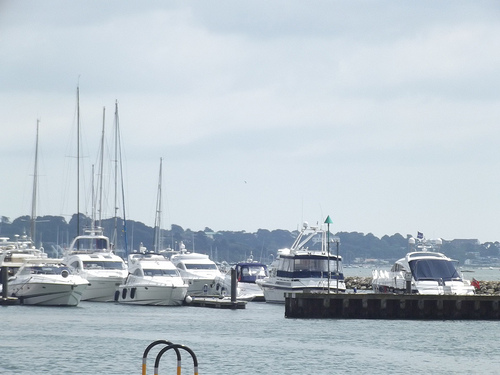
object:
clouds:
[0, 0, 497, 197]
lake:
[6, 302, 497, 373]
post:
[25, 82, 174, 258]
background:
[0, 0, 499, 237]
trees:
[391, 233, 404, 256]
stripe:
[21, 291, 87, 300]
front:
[25, 274, 88, 307]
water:
[1, 304, 497, 374]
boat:
[392, 243, 484, 335]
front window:
[404, 257, 457, 280]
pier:
[270, 249, 497, 344]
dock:
[285, 291, 498, 321]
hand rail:
[136, 334, 201, 372]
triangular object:
[322, 215, 332, 227]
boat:
[6, 260, 91, 310]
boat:
[63, 163, 125, 300]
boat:
[116, 250, 187, 306]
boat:
[171, 250, 226, 297]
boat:
[253, 220, 348, 302]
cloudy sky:
[0, 0, 499, 230]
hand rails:
[138, 335, 200, 372]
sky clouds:
[0, 8, 499, 211]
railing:
[306, 291, 344, 295]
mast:
[71, 84, 83, 252]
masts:
[147, 155, 169, 255]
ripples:
[0, 321, 500, 373]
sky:
[1, 0, 490, 235]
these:
[28, 116, 40, 232]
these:
[14, 211, 438, 344]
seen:
[0, 25, 499, 374]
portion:
[151, 347, 194, 375]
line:
[35, 327, 482, 368]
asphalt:
[279, 250, 476, 324]